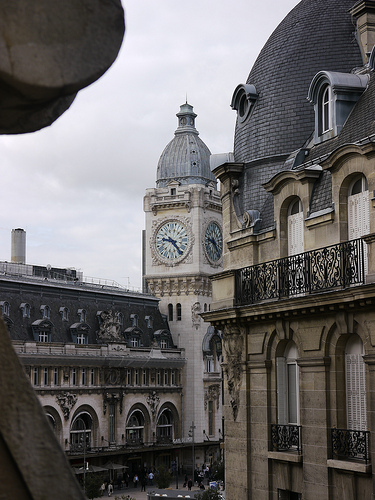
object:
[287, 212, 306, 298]
shutters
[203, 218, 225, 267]
clock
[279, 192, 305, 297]
arched window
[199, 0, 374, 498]
building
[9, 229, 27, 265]
smoke stack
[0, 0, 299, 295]
sky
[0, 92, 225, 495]
building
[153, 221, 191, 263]
clock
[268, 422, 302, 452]
metal railing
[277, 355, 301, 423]
window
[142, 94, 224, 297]
tower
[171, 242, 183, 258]
hands